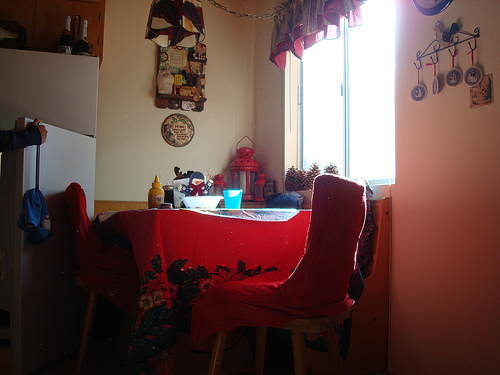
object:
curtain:
[264, 0, 383, 69]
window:
[237, 1, 419, 208]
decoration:
[160, 112, 195, 148]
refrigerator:
[14, 124, 99, 370]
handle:
[35, 122, 42, 202]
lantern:
[229, 134, 265, 203]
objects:
[408, 17, 488, 104]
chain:
[190, 0, 289, 21]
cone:
[296, 168, 306, 190]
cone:
[285, 167, 296, 191]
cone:
[323, 165, 339, 175]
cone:
[308, 164, 320, 189]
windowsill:
[282, 177, 394, 194]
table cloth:
[92, 195, 313, 375]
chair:
[191, 174, 370, 375]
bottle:
[147, 173, 166, 208]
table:
[92, 205, 310, 366]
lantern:
[209, 172, 226, 197]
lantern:
[253, 174, 267, 202]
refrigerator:
[2, 52, 99, 372]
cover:
[308, 177, 364, 307]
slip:
[112, 192, 317, 292]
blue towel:
[16, 188, 51, 244]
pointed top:
[153, 173, 159, 187]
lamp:
[146, 5, 201, 48]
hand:
[28, 116, 51, 145]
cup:
[223, 189, 244, 210]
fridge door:
[12, 114, 117, 372]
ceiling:
[142, 1, 311, 30]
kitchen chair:
[188, 172, 369, 375]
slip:
[188, 169, 368, 346]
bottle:
[57, 13, 73, 56]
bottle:
[75, 18, 92, 59]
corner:
[231, 2, 285, 199]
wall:
[386, 4, 498, 369]